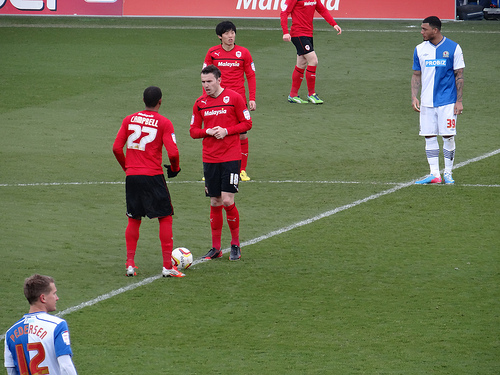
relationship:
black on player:
[124, 173, 170, 221] [112, 87, 178, 295]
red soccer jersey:
[116, 107, 174, 182] [188, 89, 246, 161]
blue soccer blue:
[410, 39, 462, 110] [410, 36, 465, 110]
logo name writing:
[424, 58, 451, 71] [420, 58, 452, 70]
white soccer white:
[413, 106, 457, 137] [413, 99, 463, 137]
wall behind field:
[3, 0, 247, 21] [0, 15, 170, 120]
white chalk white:
[316, 192, 389, 220] [240, 178, 422, 255]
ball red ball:
[170, 246, 195, 269] [172, 246, 197, 271]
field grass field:
[0, 15, 500, 375] [0, 15, 170, 120]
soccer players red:
[99, 0, 355, 291] [116, 107, 174, 182]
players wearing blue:
[403, 17, 465, 186] [410, 39, 462, 110]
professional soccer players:
[0, 5, 471, 351] [7, 8, 477, 358]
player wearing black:
[112, 87, 178, 295] [124, 173, 170, 221]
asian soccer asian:
[205, 15, 249, 59] [196, 15, 257, 113]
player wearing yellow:
[284, 0, 331, 115] [279, 91, 324, 110]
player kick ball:
[112, 87, 178, 295] [172, 246, 197, 271]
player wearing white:
[404, 19, 468, 191] [413, 99, 463, 137]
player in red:
[112, 87, 178, 295] [116, 107, 174, 182]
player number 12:
[7, 267, 88, 374] [7, 343, 46, 374]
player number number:
[404, 19, 468, 191] [444, 115, 462, 131]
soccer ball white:
[99, 0, 355, 291] [240, 178, 422, 255]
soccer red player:
[104, 0, 341, 289] [112, 87, 178, 295]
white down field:
[240, 178, 422, 255] [0, 15, 170, 120]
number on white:
[444, 115, 462, 126] [413, 99, 463, 137]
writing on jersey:
[420, 58, 452, 70] [188, 89, 246, 161]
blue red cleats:
[444, 172, 456, 183] [415, 170, 453, 190]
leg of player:
[416, 132, 458, 168] [404, 19, 468, 191]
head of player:
[194, 68, 225, 99] [205, 74, 246, 258]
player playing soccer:
[7, 267, 88, 374] [99, 0, 355, 291]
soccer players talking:
[99, 0, 355, 291] [133, 71, 227, 116]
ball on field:
[172, 246, 197, 271] [0, 15, 170, 120]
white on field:
[240, 178, 422, 255] [0, 15, 170, 120]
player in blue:
[404, 19, 468, 191] [410, 39, 462, 110]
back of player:
[114, 109, 171, 182] [112, 87, 178, 295]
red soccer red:
[205, 202, 243, 250] [205, 202, 243, 250]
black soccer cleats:
[206, 247, 243, 262] [209, 244, 246, 266]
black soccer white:
[124, 173, 170, 221] [413, 99, 463, 137]